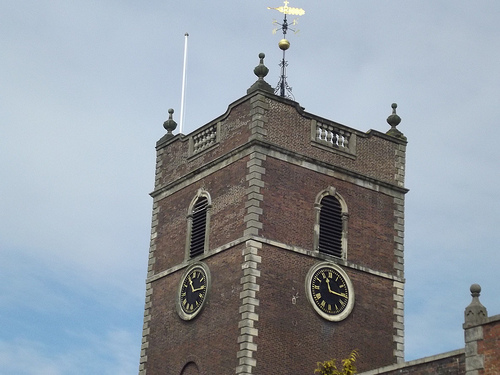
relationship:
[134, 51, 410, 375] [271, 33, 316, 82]
building has tip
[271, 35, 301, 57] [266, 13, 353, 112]
ball on vane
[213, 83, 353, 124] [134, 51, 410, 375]
top of building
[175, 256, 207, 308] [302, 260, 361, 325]
hand on clock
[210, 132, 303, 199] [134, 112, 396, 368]
color on building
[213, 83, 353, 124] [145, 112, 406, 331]
top of buliding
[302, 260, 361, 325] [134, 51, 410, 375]
clock on building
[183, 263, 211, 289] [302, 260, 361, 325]
hands on clock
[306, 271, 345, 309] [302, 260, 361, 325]
numbers on clock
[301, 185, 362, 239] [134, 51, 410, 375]
window on building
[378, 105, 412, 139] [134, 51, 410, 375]
spire on building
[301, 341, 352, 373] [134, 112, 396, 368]
tree by building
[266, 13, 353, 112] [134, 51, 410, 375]
vane on building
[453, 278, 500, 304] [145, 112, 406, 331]
knob on buliding